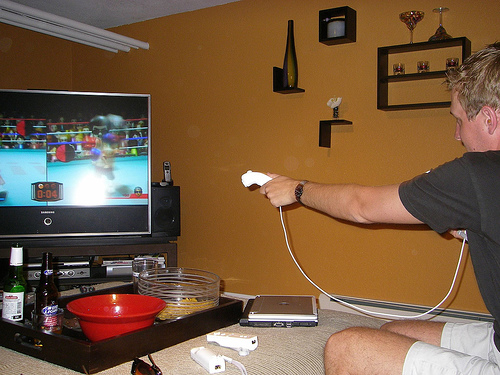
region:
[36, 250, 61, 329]
An open bud light bottle.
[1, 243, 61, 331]
Green and brown beer bottles.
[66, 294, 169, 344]
Plastic red bowl tray.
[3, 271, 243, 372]
Dark brown wooden bowl.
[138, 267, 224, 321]
Clear striped glass bowl.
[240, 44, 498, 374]
Man playing the wii game.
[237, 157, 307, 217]
Man holding a wii game controller.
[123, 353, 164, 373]
Brown sunglasses on sofa.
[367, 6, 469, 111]
Shelf with glasses on it.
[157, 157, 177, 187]
Cordless phone sitting on a speaker.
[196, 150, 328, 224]
The man is holding a wii controller.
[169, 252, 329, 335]
The laptop sitting on bed.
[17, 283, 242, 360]
A food tray on the bed.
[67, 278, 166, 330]
A red bowl in the tray.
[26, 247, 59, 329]
A bottle of beer on the tray.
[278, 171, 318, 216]
The man is wearing a watch.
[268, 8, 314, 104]
A vase on the shelf.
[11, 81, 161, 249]
Television on the tv stand.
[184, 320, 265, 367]
White controllers on the bed.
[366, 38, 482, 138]
A shelf on the wall.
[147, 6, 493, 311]
brown wall with objects on angled black shelves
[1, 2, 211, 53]
row of pipes below white ceiling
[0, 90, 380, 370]
television and black tray on large beige cushion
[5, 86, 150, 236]
television screen showing boxing match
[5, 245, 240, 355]
dark bottles and bowls on tray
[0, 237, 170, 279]
electronic devices below screen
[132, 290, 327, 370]
game controllers between sunglasses and laptop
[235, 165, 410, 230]
game controller at end of man's extended arm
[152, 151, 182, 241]
telephone on top of speaker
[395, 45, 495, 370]
man watching screen in black shirt and shorts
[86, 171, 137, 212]
this is a television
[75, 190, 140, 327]
this is a samsung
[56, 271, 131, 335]
this is a red bowl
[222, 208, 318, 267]
this is a wii remote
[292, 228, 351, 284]
this is a wii cable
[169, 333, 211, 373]
the wii is white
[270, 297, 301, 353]
this is a laptop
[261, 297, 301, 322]
the laptop is windows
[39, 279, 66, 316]
this is a beer bottle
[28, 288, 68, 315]
the bottle is dark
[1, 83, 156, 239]
some kind of video game is displayed on the TV screen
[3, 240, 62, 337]
someone has been enjoying a couple of beers today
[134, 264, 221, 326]
a snack bowl is still partly full of snack food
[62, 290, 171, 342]
a red bowl sits in a loose desk drawer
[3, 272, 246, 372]
a desk drawer is being used as a food tray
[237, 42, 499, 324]
the video game player uses body English to play the game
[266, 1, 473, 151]
shadowbox-type decorations hang on the wall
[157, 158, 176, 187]
a cell phone sits atop a speaker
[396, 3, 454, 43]
these glasses were cut in half to occupy the shadowbox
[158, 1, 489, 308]
the wall is sort of light brown